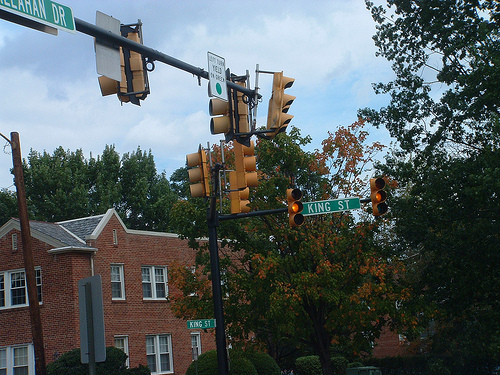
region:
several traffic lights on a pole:
[172, 143, 270, 365]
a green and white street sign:
[297, 175, 365, 222]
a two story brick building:
[14, 219, 239, 374]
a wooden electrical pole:
[0, 117, 60, 373]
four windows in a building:
[113, 246, 173, 373]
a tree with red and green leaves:
[251, 121, 373, 339]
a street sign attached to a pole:
[177, 300, 226, 347]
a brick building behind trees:
[342, 256, 429, 368]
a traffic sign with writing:
[200, 47, 235, 104]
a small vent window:
[106, 225, 123, 257]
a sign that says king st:
[290, 178, 382, 243]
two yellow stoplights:
[266, 174, 463, 276]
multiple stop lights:
[91, 43, 402, 232]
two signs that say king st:
[154, 133, 401, 350]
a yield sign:
[188, 25, 247, 115]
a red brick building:
[10, 184, 308, 359]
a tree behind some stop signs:
[157, 40, 404, 359]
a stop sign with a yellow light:
[278, 190, 321, 228]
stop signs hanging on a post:
[173, 47, 301, 240]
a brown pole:
[7, 108, 67, 365]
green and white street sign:
[170, 313, 229, 333]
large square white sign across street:
[190, 43, 255, 108]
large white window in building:
[130, 256, 175, 297]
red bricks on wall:
[115, 313, 178, 328]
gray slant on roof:
[71, 221, 90, 236]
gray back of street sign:
[65, 268, 125, 348]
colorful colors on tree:
[350, 248, 422, 340]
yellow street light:
[279, 183, 326, 223]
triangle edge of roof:
[86, 203, 148, 253]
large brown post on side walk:
[3, 121, 53, 359]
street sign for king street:
[296, 195, 360, 215]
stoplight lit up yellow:
[284, 183, 305, 230]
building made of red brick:
[1, 207, 486, 373]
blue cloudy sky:
[298, 9, 365, 105]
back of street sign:
[76, 272, 107, 373]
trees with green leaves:
[44, 143, 159, 201]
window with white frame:
[138, 262, 170, 303]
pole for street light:
[4, 126, 59, 373]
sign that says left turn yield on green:
[207, 49, 230, 103]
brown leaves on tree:
[312, 112, 372, 190]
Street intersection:
[78, 64, 353, 281]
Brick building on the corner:
[81, 207, 211, 355]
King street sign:
[275, 186, 420, 261]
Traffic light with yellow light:
[265, 158, 377, 326]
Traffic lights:
[171, 105, 459, 310]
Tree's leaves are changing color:
[163, 149, 405, 341]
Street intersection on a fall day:
[53, 25, 464, 310]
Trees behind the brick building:
[36, 133, 175, 210]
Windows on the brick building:
[103, 253, 218, 357]